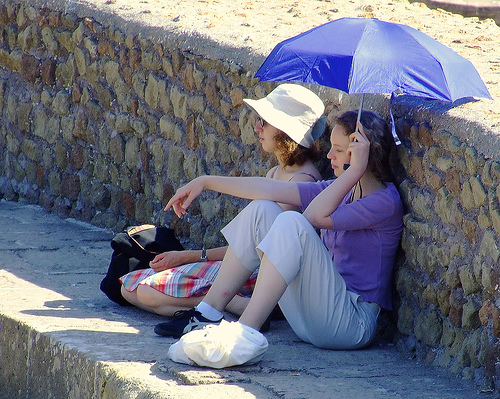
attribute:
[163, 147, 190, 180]
brick — small, grey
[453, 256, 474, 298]
brick — small, grey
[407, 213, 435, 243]
brick — small, grey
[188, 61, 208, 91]
brick — small, grey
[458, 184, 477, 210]
brick — small, grey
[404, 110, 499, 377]
wall — small, grey, brick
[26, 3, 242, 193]
wall — small, grey, brick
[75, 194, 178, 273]
bag — black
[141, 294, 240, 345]
shoe — black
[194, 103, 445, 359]
girls — sitting down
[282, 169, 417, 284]
shirt — purple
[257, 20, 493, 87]
umbrella — opened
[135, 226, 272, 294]
skirt — colorful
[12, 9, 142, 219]
wall — leaning 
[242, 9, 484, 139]
umbrella — blue , top 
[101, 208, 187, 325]
bag — ground 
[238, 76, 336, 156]
hat — woman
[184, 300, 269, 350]
sock — woman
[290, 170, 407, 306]
shirt — purple 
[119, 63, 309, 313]
girl — white sun hat.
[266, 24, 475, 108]
umbrella — blue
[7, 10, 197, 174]
wall — stone, rock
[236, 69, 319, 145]
hat — white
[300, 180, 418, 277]
shirt — purple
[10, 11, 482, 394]
scene — outdoors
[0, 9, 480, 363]
scene — outdoors